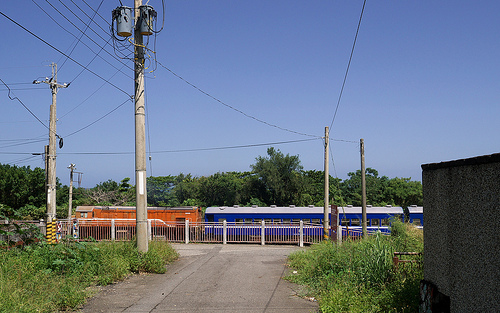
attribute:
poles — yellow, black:
[40, 212, 64, 253]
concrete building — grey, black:
[422, 148, 497, 310]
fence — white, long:
[168, 221, 322, 245]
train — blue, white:
[56, 146, 436, 292]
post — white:
[297, 217, 309, 247]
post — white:
[259, 212, 267, 241]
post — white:
[219, 215, 229, 242]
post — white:
[179, 210, 191, 244]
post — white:
[105, 211, 115, 241]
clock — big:
[235, 178, 253, 207]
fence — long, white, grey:
[40, 182, 384, 274]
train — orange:
[69, 197, 202, 237]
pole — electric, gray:
[126, 95, 160, 262]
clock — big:
[367, 219, 397, 254]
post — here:
[358, 140, 367, 237]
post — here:
[324, 126, 330, 230]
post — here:
[131, 0, 148, 255]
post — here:
[67, 170, 72, 242]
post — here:
[46, 85, 56, 225]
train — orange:
[65, 163, 392, 273]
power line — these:
[3, 132, 331, 157]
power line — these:
[327, 135, 362, 145]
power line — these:
[328, 0, 370, 136]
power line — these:
[53, 90, 138, 142]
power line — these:
[41, 1, 106, 83]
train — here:
[62, 204, 429, 249]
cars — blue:
[201, 194, 346, 244]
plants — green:
[1, 225, 180, 310]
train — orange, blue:
[70, 195, 422, 237]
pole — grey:
[115, 0, 226, 251]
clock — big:
[404, 276, 453, 304]